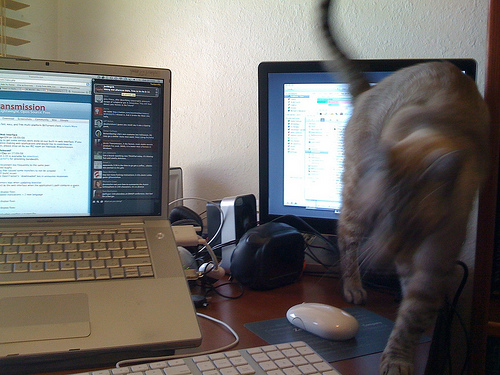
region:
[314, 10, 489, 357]
cat walking on the desk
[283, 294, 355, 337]
white wireless mouse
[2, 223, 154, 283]
built in keyboard in the laptop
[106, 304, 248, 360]
cord to the external keyboard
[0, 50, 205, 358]
open laptop on the desk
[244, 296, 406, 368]
black mousepad on the desk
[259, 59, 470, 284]
computer monitor on the desk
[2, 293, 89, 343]
trackpad on the keyboard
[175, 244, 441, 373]
desk the cat is walking on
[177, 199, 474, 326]
cords on the desk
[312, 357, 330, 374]
white key on a keyboard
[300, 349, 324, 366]
white key on a keyboard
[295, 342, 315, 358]
white key on a keyboard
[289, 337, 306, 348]
white key on a keyboard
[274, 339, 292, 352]
white key on a keyboard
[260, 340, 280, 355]
white key on a keyboard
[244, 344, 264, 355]
white key on a keyboard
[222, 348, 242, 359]
white key on a keyboard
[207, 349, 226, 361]
white key on a keyboard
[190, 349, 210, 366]
white key on a keyboard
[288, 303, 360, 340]
White wireless computer mouse.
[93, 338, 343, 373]
Additional keyboard attached to laptop.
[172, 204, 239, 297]
Messy wires from electronics.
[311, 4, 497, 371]
Gray cat in motion on desk.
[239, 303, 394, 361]
Black computer mouse pad.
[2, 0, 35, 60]
Section of blinds in window.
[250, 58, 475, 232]
Additional computer monitor on desk.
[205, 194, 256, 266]
Gray speaker on desk.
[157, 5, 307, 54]
White bumpy wall behind computer equipment.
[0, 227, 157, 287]
Keyboard on laptop computer.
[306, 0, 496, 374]
brown black and gray cat on desk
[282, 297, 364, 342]
plastic white computer mouse on desk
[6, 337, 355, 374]
flat white and light gray keyboard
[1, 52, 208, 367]
gray laptop computer on desk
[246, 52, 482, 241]
black rectangular flat screen computer monitor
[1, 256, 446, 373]
wooden desk with computer on it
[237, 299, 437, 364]
square flat black mouse pad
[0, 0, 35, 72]
light beige window blinds near laptop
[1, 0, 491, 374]
white wall next to wooden desk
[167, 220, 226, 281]
white plastic connector cable